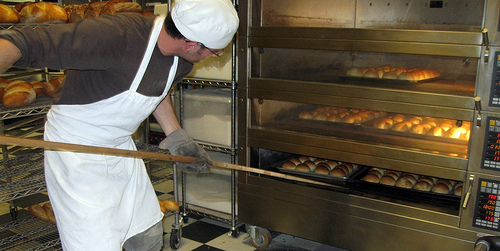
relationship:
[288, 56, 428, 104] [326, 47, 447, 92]
pan has bread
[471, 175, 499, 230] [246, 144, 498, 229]
controls on oven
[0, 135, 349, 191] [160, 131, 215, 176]
pan handle in hand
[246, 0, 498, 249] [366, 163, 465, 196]
pan of bread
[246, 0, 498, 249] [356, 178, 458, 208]
pan in oven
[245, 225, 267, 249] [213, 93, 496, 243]
wheel supporting oven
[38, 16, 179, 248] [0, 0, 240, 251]
white apron on man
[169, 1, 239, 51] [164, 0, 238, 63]
hat on head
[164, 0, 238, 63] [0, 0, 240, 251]
head on man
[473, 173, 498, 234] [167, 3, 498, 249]
front buttons on commercial oven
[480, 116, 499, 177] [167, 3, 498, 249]
front buttons on commercial oven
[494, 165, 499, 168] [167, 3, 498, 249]
front buttons on commercial oven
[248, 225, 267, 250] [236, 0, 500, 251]
wheel on commercial oven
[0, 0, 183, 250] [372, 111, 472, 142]
rack with bread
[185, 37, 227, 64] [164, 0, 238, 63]
eyeglasses on head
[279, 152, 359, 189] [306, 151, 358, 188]
pan of bread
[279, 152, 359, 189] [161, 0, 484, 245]
pan in oven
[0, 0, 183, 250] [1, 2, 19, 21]
rack with bread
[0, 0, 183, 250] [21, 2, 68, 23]
rack with bread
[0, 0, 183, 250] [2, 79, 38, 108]
rack with bread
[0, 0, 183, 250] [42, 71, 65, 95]
rack with bread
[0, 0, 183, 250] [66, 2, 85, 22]
rack with bread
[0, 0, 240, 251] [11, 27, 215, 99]
man wearing sweater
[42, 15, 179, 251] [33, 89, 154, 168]
white apron around waist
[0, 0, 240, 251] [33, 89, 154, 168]
man has waist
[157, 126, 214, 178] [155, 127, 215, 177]
glove on hand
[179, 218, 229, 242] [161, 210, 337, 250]
tile on floor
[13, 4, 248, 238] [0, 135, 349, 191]
man with pan handle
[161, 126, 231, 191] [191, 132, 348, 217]
glove on handle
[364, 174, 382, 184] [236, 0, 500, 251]
bread inside commercial oven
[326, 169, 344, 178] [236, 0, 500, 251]
bread inside commercial oven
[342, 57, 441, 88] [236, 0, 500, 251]
buns inside commercial oven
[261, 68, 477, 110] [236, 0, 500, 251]
shelf of commercial oven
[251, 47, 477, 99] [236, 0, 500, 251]
shelf of commercial oven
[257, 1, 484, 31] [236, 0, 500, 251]
shelf of commercial oven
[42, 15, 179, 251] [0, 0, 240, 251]
white apron on man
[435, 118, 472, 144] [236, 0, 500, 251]
light in commercial oven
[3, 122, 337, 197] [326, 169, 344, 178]
pan handle for bread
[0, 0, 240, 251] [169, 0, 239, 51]
man wearing hat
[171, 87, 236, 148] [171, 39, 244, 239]
box on rack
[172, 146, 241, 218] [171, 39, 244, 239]
box on rack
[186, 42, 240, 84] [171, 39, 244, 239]
box on rack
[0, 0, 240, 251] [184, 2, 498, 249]
man working in bakery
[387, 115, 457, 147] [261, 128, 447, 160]
bread on metal rack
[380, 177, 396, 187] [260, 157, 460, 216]
buns baking in a pan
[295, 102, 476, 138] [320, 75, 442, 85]
bread baking in a pan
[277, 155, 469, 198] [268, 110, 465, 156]
bread baking in a pan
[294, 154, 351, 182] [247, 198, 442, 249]
bread on a stand